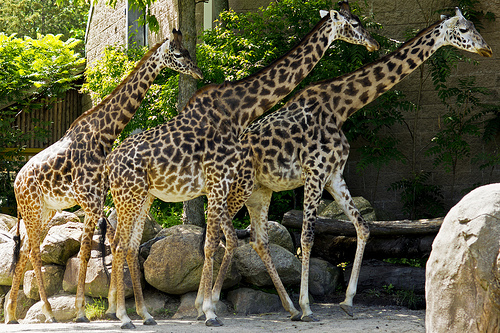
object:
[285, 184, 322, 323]
leg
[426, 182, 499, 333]
boulder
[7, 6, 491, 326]
line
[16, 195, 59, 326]
leg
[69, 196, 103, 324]
leg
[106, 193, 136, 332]
leg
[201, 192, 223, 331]
leg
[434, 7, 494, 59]
head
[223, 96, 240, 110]
spot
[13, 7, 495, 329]
giraffes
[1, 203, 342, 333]
rocks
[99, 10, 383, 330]
giraffe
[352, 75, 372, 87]
brown spot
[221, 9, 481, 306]
giraffe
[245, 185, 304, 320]
leg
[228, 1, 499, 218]
wall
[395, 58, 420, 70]
spot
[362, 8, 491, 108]
elbow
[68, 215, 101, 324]
leg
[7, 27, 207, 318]
giraffe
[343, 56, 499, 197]
wall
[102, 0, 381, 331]
giraffe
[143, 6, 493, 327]
giraffe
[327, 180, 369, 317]
leg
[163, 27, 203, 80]
head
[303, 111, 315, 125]
spot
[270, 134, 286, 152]
spot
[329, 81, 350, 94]
spot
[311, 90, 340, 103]
spot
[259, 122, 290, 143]
spot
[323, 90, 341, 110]
spot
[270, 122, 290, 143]
spot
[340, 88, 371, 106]
spot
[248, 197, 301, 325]
leg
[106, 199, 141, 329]
leg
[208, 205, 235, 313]
leg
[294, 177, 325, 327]
leg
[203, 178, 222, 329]
leg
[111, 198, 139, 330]
leg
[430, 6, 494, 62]
head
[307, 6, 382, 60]
head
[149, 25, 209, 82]
head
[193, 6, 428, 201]
trees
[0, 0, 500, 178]
background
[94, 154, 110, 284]
tail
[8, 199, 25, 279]
tail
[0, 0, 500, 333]
zoo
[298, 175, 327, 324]
leg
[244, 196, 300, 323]
leg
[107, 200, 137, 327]
leg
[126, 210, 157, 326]
leg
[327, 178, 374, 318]
leg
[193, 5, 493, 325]
giraffe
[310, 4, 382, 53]
head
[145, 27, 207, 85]
head